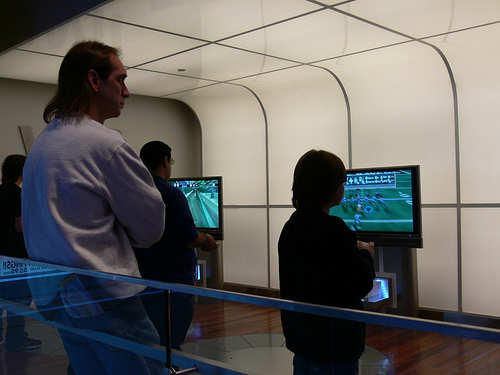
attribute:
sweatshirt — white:
[19, 114, 171, 316]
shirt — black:
[279, 211, 371, 351]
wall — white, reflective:
[2, 6, 499, 323]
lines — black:
[452, 85, 464, 320]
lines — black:
[262, 115, 272, 287]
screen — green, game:
[181, 175, 223, 232]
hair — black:
[294, 149, 347, 214]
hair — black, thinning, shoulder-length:
[36, 38, 124, 127]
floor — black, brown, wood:
[2, 299, 497, 372]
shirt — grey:
[22, 115, 165, 303]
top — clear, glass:
[62, 269, 364, 374]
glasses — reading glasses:
[168, 158, 178, 167]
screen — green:
[335, 168, 417, 238]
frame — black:
[204, 173, 229, 241]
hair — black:
[4, 152, 26, 178]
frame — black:
[342, 163, 422, 248]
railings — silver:
[2, 251, 483, 371]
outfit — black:
[274, 210, 377, 372]